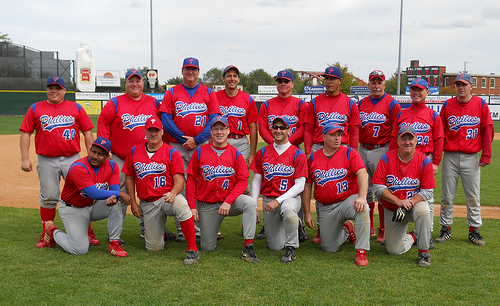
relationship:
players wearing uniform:
[39, 47, 494, 265] [309, 97, 362, 141]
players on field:
[39, 47, 494, 265] [126, 243, 396, 302]